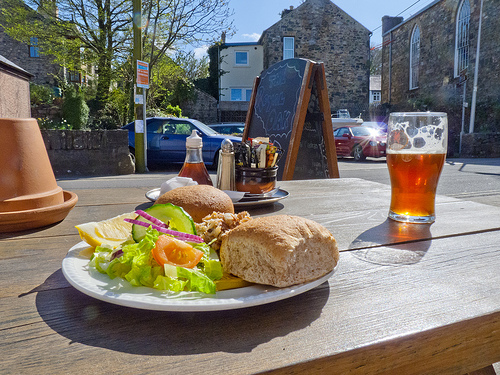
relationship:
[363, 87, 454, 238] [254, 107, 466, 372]
glass on table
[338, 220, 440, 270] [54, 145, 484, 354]
shadow table on table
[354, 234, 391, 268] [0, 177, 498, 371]
line on table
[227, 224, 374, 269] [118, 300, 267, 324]
bread on plate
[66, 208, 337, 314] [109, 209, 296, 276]
plate under food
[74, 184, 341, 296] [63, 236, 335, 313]
food on a plate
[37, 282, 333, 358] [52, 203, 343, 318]
shadow of plate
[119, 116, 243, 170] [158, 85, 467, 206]
blue car in background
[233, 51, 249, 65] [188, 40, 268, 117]
window on building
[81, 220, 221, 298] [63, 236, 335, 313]
lettuce on plate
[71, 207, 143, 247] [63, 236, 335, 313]
lemon on plate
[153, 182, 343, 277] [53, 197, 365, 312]
rolls on plate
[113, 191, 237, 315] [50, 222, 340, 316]
salad on plate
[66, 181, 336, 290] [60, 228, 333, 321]
food on plate